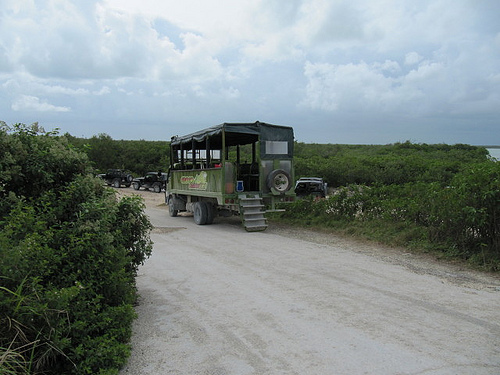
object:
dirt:
[310, 278, 407, 343]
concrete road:
[114, 185, 500, 375]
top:
[170, 120, 295, 167]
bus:
[163, 120, 296, 233]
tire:
[192, 201, 215, 225]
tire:
[166, 198, 178, 217]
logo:
[178, 170, 207, 190]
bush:
[83, 132, 123, 172]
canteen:
[265, 167, 293, 193]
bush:
[268, 140, 499, 273]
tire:
[265, 168, 293, 196]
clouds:
[2, 0, 499, 146]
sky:
[1, 0, 500, 149]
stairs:
[238, 192, 268, 232]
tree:
[272, 159, 500, 272]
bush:
[2, 120, 160, 375]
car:
[131, 172, 168, 193]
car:
[98, 169, 134, 188]